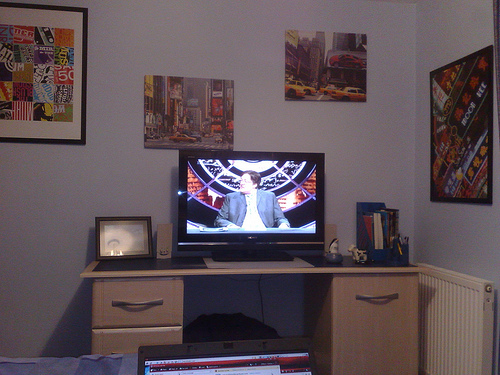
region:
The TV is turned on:
[175, 146, 326, 258]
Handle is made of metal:
[111, 299, 165, 307]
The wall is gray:
[2, 1, 414, 355]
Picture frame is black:
[95, 216, 150, 258]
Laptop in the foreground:
[140, 336, 311, 373]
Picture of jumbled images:
[0, 27, 75, 123]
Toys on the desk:
[330, 238, 367, 263]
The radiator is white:
[417, 262, 494, 374]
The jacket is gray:
[214, 189, 286, 229]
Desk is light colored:
[79, 253, 424, 373]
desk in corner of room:
[16, 133, 486, 364]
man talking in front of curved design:
[175, 142, 332, 257]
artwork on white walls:
[5, 5, 495, 355]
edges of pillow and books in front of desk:
[0, 347, 318, 372]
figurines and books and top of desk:
[325, 195, 410, 265]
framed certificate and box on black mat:
[82, 205, 207, 270]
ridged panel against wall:
[410, 250, 492, 370]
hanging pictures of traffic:
[140, 20, 370, 145]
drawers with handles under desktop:
[85, 262, 420, 369]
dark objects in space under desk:
[181, 280, 327, 355]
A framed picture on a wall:
[0, 1, 89, 145]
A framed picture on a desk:
[95, 215, 153, 259]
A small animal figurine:
[347, 244, 367, 264]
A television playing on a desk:
[178, 150, 323, 242]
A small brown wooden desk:
[85, 248, 422, 373]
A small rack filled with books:
[355, 199, 400, 262]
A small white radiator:
[418, 263, 490, 373]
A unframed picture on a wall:
[142, 76, 232, 147]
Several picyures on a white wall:
[0, 2, 496, 207]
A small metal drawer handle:
[112, 297, 161, 308]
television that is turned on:
[133, 128, 353, 257]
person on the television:
[215, 167, 278, 239]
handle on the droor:
[107, 283, 181, 325]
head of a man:
[238, 169, 263, 196]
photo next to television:
[87, 199, 169, 280]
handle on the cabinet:
[353, 279, 404, 324]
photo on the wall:
[259, 23, 391, 130]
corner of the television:
[301, 135, 338, 184]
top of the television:
[167, 144, 337, 169]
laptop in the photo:
[130, 325, 333, 372]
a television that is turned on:
[180, 147, 326, 245]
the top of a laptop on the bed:
[140, 339, 314, 374]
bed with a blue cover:
[5, 355, 136, 373]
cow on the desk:
[349, 245, 367, 264]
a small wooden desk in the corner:
[90, 258, 413, 374]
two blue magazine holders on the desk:
[357, 198, 409, 263]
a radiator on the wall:
[422, 263, 497, 374]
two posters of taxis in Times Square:
[142, 28, 368, 152]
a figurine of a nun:
[330, 238, 340, 254]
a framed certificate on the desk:
[94, 214, 156, 263]